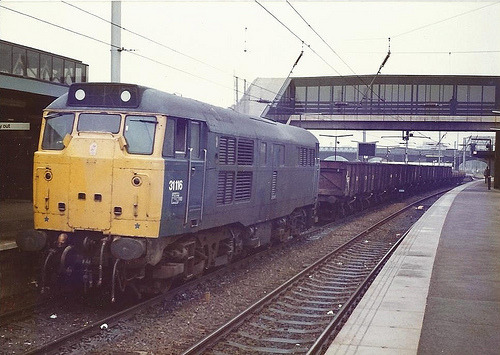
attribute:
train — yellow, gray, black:
[17, 82, 467, 301]